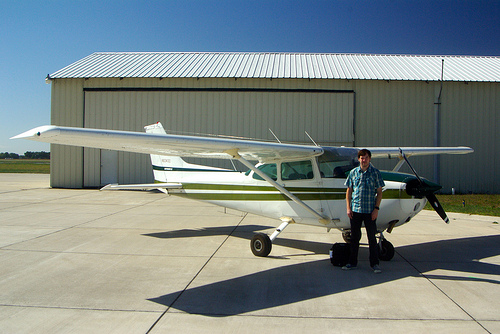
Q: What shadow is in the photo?
A: Airplane.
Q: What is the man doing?
A: Getting ready to fly the plane.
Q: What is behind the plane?
A: Metal building.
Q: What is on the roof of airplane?
A: White roof of airplane hangar.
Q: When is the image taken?
A: When plane is landed.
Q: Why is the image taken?
A: Remembrance.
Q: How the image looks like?
A: Pretty good.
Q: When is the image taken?
A: When man is standing side to the plane.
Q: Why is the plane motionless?
A: Its landed.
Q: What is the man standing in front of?
A: A plane.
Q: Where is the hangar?
A: Behind the plane.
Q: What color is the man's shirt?
A: Teal.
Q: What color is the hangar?
A: White.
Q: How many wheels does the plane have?
A: 4.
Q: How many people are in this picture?
A: 1.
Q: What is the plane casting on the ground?
A: A shadow.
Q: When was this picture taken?
A: Daytime.